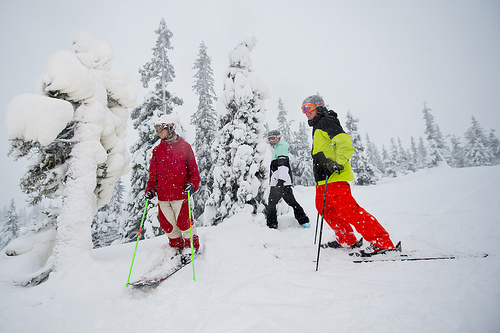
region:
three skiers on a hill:
[126, 92, 403, 267]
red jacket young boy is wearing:
[142, 138, 200, 200]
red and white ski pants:
[157, 202, 201, 249]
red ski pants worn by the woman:
[316, 183, 393, 251]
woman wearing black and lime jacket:
[308, 111, 355, 185]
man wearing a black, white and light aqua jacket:
[269, 142, 293, 187]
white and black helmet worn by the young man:
[155, 115, 175, 140]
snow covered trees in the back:
[1, 2, 496, 287]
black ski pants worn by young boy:
[266, 185, 310, 230]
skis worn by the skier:
[126, 242, 205, 287]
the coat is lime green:
[323, 139, 351, 160]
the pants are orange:
[330, 200, 362, 229]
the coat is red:
[155, 160, 178, 180]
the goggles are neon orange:
[297, 103, 317, 114]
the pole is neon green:
[134, 208, 150, 233]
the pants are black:
[266, 196, 276, 209]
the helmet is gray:
[306, 97, 322, 107]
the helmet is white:
[160, 115, 172, 125]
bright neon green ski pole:
[182, 182, 198, 280]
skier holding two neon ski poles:
[121, 105, 203, 295]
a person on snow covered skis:
[120, 240, 200, 287]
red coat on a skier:
[142, 135, 202, 202]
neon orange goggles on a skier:
[300, 100, 324, 114]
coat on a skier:
[306, 105, 361, 186]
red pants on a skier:
[314, 179, 399, 249]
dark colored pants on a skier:
[264, 183, 311, 229]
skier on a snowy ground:
[259, 128, 311, 229]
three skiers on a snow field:
[121, 93, 406, 304]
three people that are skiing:
[105, 89, 444, 304]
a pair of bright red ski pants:
[300, 185, 402, 254]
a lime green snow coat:
[312, 125, 374, 195]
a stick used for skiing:
[302, 182, 342, 274]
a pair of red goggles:
[297, 92, 322, 124]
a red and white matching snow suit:
[133, 134, 205, 258]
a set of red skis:
[126, 239, 211, 306]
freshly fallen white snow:
[221, 267, 308, 331]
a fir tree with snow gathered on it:
[25, 35, 130, 257]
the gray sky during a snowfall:
[340, 42, 408, 104]